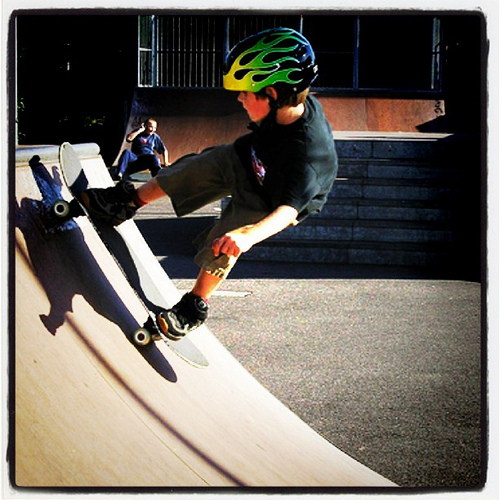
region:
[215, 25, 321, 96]
helmet with flame pattern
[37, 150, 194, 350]
skateboard going up ramp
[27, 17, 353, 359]
Kid skating on ramp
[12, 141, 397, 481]
Skating ramp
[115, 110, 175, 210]
skater sitting on ramp next to his skateboard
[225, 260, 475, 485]
flat area between ramps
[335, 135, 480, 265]
steps for performing tricks like grinds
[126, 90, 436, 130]
Another ramp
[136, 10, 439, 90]
safety fence at top of ramp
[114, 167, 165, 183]
skateboard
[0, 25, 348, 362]
a boy on a skate board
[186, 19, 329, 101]
a boy wearing a safety helmet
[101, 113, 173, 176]
a man sitting down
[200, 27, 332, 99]
a green, yellow and black helmet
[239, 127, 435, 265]
a concrete wall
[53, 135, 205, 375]
a black skateboard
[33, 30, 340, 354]
a boy doing a stunt on a skateboard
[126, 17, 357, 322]
a man watching a child skateboard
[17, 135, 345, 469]
a wall for riding skate boards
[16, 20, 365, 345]
a young boy wearing a black shirt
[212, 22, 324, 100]
black helmet with green and yellow flames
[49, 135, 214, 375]
black skateboard with white wheels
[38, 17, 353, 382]
boy in a black shirt skateboarding up a ramp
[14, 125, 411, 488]
brown wooden ramp with a black top edge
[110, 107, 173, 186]
man in a dark shirt sitting on the stairs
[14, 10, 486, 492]
concrete skate park with wooden ramps and grey stairs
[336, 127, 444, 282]
grey staircase with 6 steps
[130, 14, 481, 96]
screen enclosure with white posts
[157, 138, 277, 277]
tan pair of shorts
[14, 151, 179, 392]
black shadow of a skateboard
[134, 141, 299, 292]
The kid is wearing shorts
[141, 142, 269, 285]
The kid is wearing colored shorts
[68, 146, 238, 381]
The kid is wearing shoes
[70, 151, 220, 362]
The kid is wearing black shoes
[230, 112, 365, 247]
The kid is wearing a shirt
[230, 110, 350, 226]
The kid is wearing a black shirt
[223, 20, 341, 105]
The kid is wearing a helmet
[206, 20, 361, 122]
The kid is wearing a yellow, green and black helmet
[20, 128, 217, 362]
The kid is on a skateboard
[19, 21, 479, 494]
The picture was taken outside on a sunny day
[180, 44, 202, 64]
section of window grills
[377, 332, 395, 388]
section of a road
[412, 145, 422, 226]
part of a stair case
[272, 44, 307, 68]
helmet of a boy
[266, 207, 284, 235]
left arm of a boy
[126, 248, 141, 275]
section of a skate board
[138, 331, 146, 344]
wheels of a skate board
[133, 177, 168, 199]
right leg of a skater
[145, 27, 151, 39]
part of a window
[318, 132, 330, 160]
back part of a boy